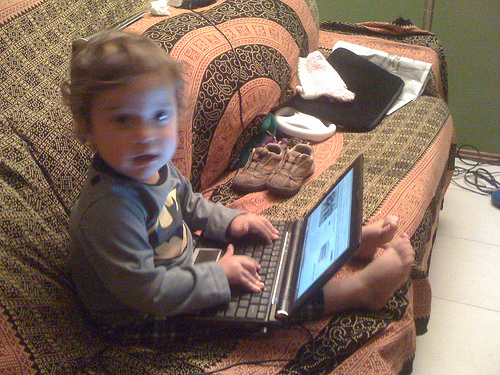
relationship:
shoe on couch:
[233, 142, 285, 191] [109, 24, 363, 198]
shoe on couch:
[265, 141, 312, 195] [6, 2, 461, 367]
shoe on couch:
[233, 142, 285, 191] [6, 2, 461, 367]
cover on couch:
[286, 47, 402, 132] [6, 2, 461, 367]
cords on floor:
[455, 147, 498, 193] [422, 154, 498, 372]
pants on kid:
[109, 309, 229, 342] [48, 18, 420, 331]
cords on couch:
[455, 147, 499, 208] [6, 2, 461, 367]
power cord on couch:
[185, 3, 247, 144] [6, 2, 461, 367]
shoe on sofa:
[233, 142, 285, 191] [12, 30, 482, 337]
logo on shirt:
[141, 182, 184, 261] [58, 154, 277, 339]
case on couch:
[289, 34, 400, 132] [0, 0, 457, 374]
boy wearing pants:
[64, 32, 417, 350] [97, 314, 247, 348]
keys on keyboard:
[219, 247, 277, 291] [180, 220, 311, 312]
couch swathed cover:
[0, 0, 457, 374] [0, 2, 457, 373]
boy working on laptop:
[64, 32, 417, 350] [189, 159, 361, 329]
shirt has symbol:
[64, 164, 242, 329] [141, 179, 191, 269]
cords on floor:
[455, 147, 499, 208] [427, 194, 493, 369]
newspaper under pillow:
[334, 39, 433, 119] [285, 31, 415, 135]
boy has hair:
[64, 32, 417, 350] [57, 28, 188, 143]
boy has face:
[64, 32, 417, 350] [93, 72, 175, 180]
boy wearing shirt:
[64, 27, 418, 312] [59, 147, 238, 311]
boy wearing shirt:
[64, 32, 417, 350] [59, 159, 246, 319]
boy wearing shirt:
[64, 32, 417, 350] [84, 201, 233, 319]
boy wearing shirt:
[64, 32, 417, 350] [69, 152, 234, 314]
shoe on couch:
[233, 134, 286, 196] [6, 2, 461, 367]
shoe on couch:
[233, 142, 285, 191] [239, 0, 427, 152]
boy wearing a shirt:
[64, 32, 417, 350] [59, 159, 246, 319]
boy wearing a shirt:
[64, 32, 417, 350] [91, 193, 233, 305]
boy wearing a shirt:
[64, 32, 417, 350] [74, 187, 256, 304]